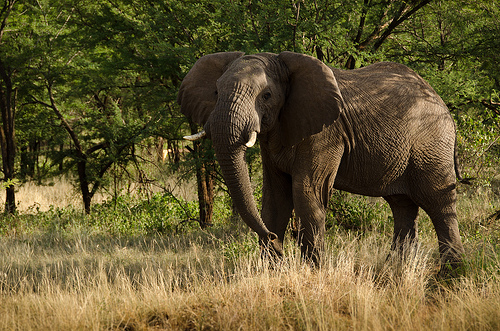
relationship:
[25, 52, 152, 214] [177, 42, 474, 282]
tree behind elephant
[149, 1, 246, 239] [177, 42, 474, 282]
tree behind elephant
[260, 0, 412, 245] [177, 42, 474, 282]
tree behind elephant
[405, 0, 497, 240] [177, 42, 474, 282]
tree behind elephant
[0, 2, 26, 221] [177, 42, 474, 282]
tree behind elephant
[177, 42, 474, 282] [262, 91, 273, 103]
elephant has black eye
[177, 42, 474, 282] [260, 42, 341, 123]
elephant has ears